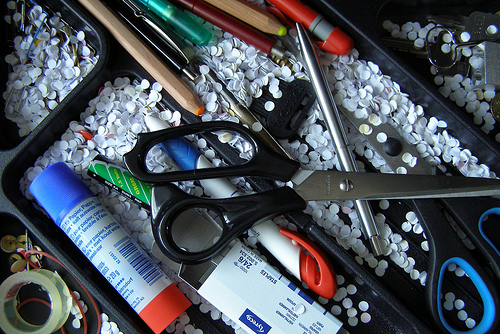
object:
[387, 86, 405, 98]
paper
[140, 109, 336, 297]
inkpen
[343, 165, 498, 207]
blade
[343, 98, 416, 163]
blade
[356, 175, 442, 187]
silver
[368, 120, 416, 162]
silver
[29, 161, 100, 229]
cap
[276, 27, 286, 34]
lead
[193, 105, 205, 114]
lead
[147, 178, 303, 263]
handle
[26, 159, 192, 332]
glue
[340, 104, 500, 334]
scissors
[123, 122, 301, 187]
handle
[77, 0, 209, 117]
pencil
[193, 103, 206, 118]
orange tip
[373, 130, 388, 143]
dot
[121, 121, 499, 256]
scissors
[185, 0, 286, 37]
pencil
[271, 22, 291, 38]
tip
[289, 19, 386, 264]
pen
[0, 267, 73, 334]
rubber bands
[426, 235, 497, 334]
handle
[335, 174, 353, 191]
screw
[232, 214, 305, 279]
barrel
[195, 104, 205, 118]
tip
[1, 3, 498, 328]
tray